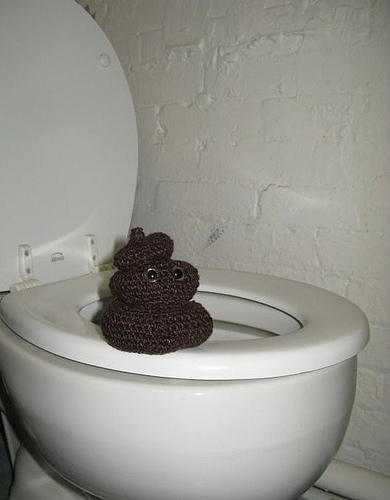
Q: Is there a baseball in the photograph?
A: No, there are no baseballs.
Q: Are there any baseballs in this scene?
A: No, there are no baseballs.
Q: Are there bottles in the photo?
A: No, there are no bottles.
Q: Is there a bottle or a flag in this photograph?
A: No, there are no bottles or flags.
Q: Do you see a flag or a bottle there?
A: No, there are no bottles or flags.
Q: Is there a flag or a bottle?
A: No, there are no bottles or flags.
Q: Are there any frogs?
A: Yes, there is a frog.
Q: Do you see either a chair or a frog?
A: Yes, there is a frog.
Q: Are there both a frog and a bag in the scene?
A: No, there is a frog but no bags.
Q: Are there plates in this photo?
A: No, there are no plates.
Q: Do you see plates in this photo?
A: No, there are no plates.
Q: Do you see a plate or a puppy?
A: No, there are no plates or puppies.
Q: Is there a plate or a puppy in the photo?
A: No, there are no plates or puppies.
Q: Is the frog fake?
A: Yes, the frog is fake.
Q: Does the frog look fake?
A: Yes, the frog is fake.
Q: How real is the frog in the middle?
A: The frog is fake.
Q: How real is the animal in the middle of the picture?
A: The frog is fake.